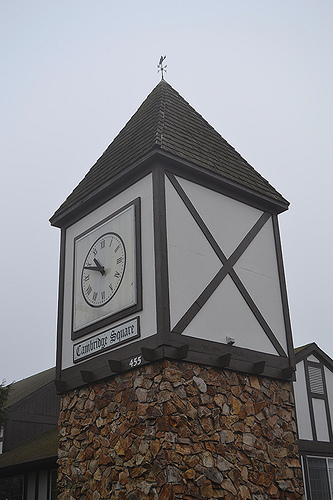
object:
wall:
[51, 353, 300, 498]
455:
[127, 354, 145, 369]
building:
[0, 367, 55, 493]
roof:
[0, 427, 60, 458]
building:
[291, 339, 333, 499]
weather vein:
[155, 52, 170, 79]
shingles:
[144, 94, 184, 149]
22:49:
[82, 235, 122, 280]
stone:
[219, 475, 237, 497]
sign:
[73, 315, 143, 364]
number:
[127, 356, 146, 367]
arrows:
[154, 64, 170, 73]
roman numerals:
[91, 289, 98, 303]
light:
[223, 334, 235, 347]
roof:
[42, 75, 297, 216]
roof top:
[47, 78, 291, 229]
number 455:
[127, 356, 147, 365]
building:
[48, 51, 300, 500]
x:
[160, 168, 291, 357]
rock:
[191, 374, 207, 393]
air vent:
[307, 363, 325, 394]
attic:
[294, 340, 333, 451]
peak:
[309, 341, 317, 353]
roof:
[293, 340, 333, 374]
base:
[55, 360, 305, 498]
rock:
[240, 429, 256, 446]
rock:
[215, 452, 233, 470]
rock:
[114, 417, 130, 433]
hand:
[89, 254, 104, 268]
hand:
[80, 264, 104, 277]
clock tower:
[47, 53, 298, 396]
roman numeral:
[98, 238, 105, 250]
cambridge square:
[75, 323, 134, 356]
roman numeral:
[107, 282, 113, 291]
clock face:
[79, 230, 127, 308]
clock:
[69, 197, 142, 336]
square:
[69, 195, 143, 340]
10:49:
[81, 225, 126, 297]